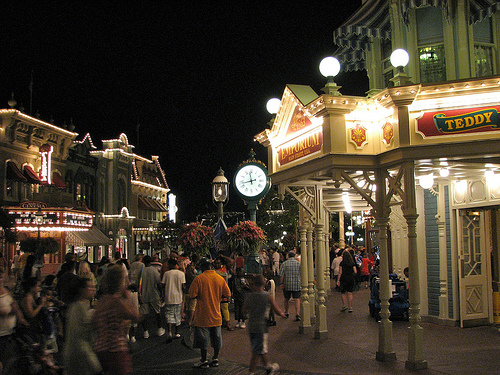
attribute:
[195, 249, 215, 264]
hat —  backwards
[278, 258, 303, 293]
shirt —  person's,  plaid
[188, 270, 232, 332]
yellow shirt —   yellow 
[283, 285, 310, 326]
shorts —  boy's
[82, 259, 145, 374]
clothes — red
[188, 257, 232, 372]
person — lots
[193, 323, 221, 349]
short —  denim,  blue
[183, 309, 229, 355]
blue shorts —  blue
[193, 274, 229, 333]
shirt —   man's,  orange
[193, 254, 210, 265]
hat —  backwards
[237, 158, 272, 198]
clock —  building's,  tall 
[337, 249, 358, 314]
woman —  in all black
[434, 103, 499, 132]
sign — teddy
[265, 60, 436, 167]
lights — illuminated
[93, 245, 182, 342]
people —  in   crowd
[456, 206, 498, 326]
door —  white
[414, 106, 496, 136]
sign —  teddy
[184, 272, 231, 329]
shirt —  orange